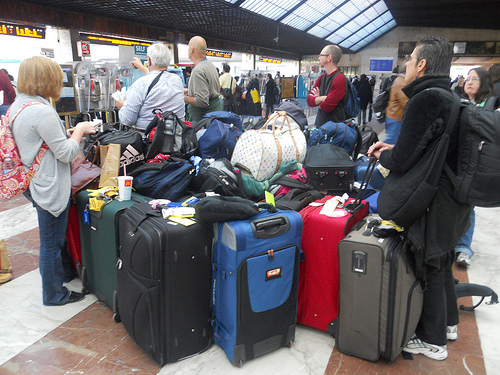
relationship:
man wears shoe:
[368, 37, 478, 366] [400, 333, 449, 363]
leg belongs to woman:
[24, 175, 72, 305] [7, 55, 100, 309]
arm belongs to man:
[369, 88, 441, 174] [368, 37, 478, 366]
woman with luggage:
[0, 55, 98, 309] [67, 99, 429, 366]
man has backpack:
[368, 37, 478, 366] [427, 88, 497, 210]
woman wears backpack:
[7, 55, 100, 309] [0, 100, 57, 202]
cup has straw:
[116, 173, 134, 202] [121, 162, 129, 176]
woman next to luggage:
[7, 55, 100, 309] [67, 99, 429, 366]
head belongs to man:
[185, 34, 206, 63] [181, 34, 223, 120]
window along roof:
[226, 1, 401, 55] [0, 1, 499, 60]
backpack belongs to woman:
[0, 100, 57, 202] [7, 55, 100, 309]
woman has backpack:
[7, 55, 100, 309] [0, 100, 57, 202]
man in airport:
[368, 37, 478, 366] [1, 2, 499, 373]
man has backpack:
[306, 44, 351, 131] [343, 73, 362, 119]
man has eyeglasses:
[306, 44, 351, 131] [318, 53, 328, 60]